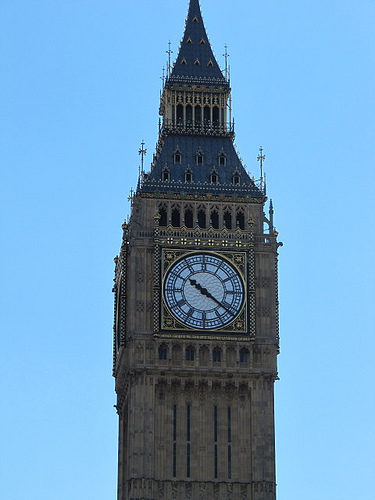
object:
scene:
[3, 2, 371, 499]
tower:
[122, 2, 280, 500]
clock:
[162, 251, 247, 333]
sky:
[6, 6, 122, 133]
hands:
[186, 278, 236, 317]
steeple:
[155, 1, 243, 140]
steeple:
[145, 0, 263, 189]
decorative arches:
[169, 97, 227, 127]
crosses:
[159, 41, 233, 76]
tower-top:
[125, 199, 294, 338]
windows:
[158, 201, 246, 231]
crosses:
[136, 144, 272, 194]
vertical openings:
[173, 399, 232, 479]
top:
[173, 2, 228, 83]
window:
[157, 203, 168, 228]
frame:
[155, 242, 252, 344]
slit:
[214, 405, 218, 443]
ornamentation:
[129, 48, 274, 244]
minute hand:
[208, 296, 235, 317]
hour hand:
[188, 277, 207, 296]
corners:
[95, 229, 154, 360]